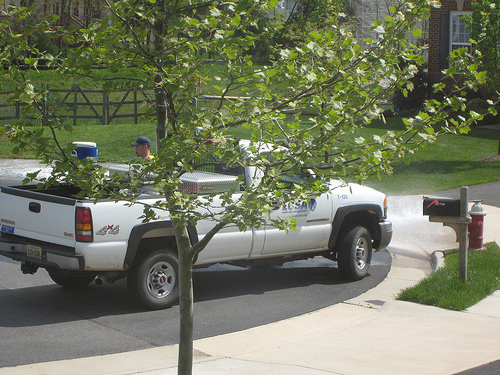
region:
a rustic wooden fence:
[13, 70, 195, 134]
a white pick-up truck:
[19, 107, 411, 296]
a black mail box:
[408, 179, 473, 233]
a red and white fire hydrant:
[454, 188, 497, 258]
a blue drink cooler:
[48, 128, 107, 180]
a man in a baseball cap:
[120, 127, 160, 174]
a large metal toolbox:
[106, 158, 258, 204]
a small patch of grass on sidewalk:
[411, 233, 497, 373]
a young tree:
[28, 7, 331, 364]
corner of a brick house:
[411, 2, 496, 141]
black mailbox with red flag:
[419, 186, 471, 238]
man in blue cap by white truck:
[127, 130, 154, 160]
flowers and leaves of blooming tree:
[353, 132, 397, 168]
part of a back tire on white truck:
[133, 250, 182, 307]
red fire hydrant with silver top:
[468, 195, 486, 253]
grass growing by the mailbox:
[418, 285, 468, 302]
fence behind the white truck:
[68, 82, 113, 125]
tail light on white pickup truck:
[65, 197, 97, 247]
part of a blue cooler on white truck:
[68, 135, 100, 162]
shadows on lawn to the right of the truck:
[425, 152, 495, 175]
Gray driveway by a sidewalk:
[271, 299, 395, 355]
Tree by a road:
[83, 53, 313, 373]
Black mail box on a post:
[411, 173, 488, 234]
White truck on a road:
[3, 153, 361, 275]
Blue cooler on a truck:
[62, 136, 106, 181]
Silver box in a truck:
[121, 141, 276, 212]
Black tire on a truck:
[330, 201, 377, 281]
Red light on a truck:
[66, 201, 108, 246]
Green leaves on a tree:
[81, 21, 390, 244]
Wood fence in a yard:
[31, 67, 184, 135]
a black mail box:
[417, 190, 465, 221]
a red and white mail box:
[465, 192, 491, 249]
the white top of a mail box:
[466, 194, 488, 219]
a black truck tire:
[333, 221, 375, 286]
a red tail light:
[71, 200, 95, 225]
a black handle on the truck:
[23, 197, 45, 214]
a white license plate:
[19, 240, 45, 262]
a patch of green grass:
[386, 237, 498, 319]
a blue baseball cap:
[126, 132, 154, 149]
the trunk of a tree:
[172, 255, 198, 374]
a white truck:
[8, 140, 404, 300]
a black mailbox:
[411, 176, 478, 291]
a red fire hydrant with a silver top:
[461, 179, 492, 261]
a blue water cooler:
[62, 126, 114, 177]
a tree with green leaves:
[28, 16, 348, 358]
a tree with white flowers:
[15, 30, 411, 325]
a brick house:
[413, 4, 497, 136]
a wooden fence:
[4, 83, 184, 138]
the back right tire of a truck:
[130, 243, 202, 314]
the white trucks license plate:
[17, 232, 64, 269]